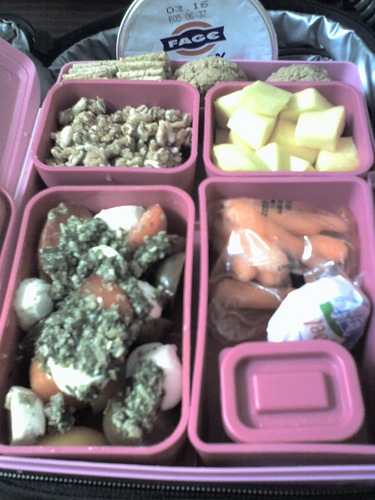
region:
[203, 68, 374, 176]
square purple plastic container with white cheese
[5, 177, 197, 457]
rectangular purple container filled with tomato and mozzerella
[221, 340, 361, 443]
small covered purple plastic container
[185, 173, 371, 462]
purple plastic container filled with carrots and wrapped cheese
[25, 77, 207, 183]
purple container of walnuts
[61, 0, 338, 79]
brown cookies and crackers with cheese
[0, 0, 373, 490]
picture of plastic containers with picnic food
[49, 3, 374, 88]
silver fabric cooler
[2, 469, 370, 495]
silver zipper around container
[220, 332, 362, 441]
square purple plastic lid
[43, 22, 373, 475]
a delicious lunch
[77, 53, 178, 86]
saltine crackers on the side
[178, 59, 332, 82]
cookies stacked on the edge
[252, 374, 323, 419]
a square shape on a container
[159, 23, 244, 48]
a logo on an applesauce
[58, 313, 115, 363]
green pesto on tomatoes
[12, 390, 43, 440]
feta cheese in a salad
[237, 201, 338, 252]
carrots in a plastic package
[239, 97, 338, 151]
diced white apple chunks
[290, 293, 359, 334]
cheese wrapped in white paper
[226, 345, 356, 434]
Pink lid in a tray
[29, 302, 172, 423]
Green food in a tray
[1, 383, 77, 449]
White food in a tray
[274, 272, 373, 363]
Wheel of cheese in a tray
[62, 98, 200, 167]
Chunky green food in a tray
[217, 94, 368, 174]
Pineapple in a pink container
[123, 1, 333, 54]
Fage yogurt in a lunch bag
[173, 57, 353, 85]
Cookies in a pink tray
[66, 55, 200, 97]
Crackers in a pink container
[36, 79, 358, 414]
Lunch in a lunch bag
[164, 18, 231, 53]
black and red label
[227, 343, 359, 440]
light pink cover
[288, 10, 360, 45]
silver edge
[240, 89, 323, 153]
slices of golden delicious apples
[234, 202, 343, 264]
red carrots in plastic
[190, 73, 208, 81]
groove in oatmeal cookie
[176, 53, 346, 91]
couple of oatmeal cookies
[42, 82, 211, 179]
pink tub of nuts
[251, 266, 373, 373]
white paper covered sandwich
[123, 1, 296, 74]
carton on yogurt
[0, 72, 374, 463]
purple plastic containers with food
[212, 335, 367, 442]
plastic lid that snaps into place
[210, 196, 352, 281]
a plastic bag of carrots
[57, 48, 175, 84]
two rows of crackers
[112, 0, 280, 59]
container of Greek yogurt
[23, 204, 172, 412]
potato an carrot and something else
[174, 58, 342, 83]
three cookies for dessert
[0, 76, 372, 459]
two large and two smaller containers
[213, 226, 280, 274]
a reflection from the plastic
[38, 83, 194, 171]
a container of unidentifiable food